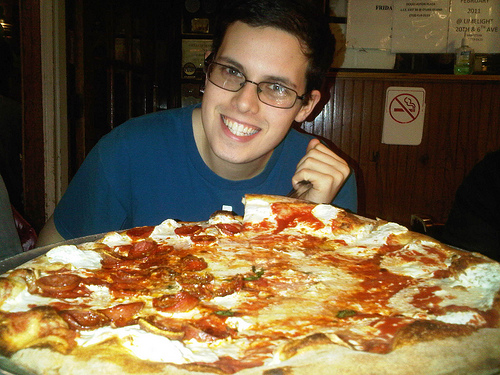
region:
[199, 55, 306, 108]
Pair of glasses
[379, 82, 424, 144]
No smoking sign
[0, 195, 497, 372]
Pizza on a metal pan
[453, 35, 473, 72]
Bottle of hand sanitizer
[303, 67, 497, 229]
Wall with metal panelling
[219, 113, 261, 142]
Young man's mouth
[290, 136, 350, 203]
Hand holding a metal spatula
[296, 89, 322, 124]
Young man's ear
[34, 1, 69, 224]
White wooden panel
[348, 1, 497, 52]
White laminated papers on the back wall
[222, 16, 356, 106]
boy has dark hair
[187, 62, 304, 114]
boy is wearing glasses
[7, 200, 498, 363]
pizza in front of boy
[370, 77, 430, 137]
red and white no smoking sign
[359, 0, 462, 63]
laminated papers in back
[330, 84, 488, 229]
brown wall around no smoking sign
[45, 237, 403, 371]
white cheese on pizza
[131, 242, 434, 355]
red sauce on pizza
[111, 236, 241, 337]
red pepperoni on pizza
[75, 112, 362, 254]
boy has blue shirt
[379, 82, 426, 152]
A no smoking sign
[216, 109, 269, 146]
Wide smile with white teeth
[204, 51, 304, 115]
A man wearing lead frame glasses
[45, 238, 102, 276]
Mozzarella cheese on a pizza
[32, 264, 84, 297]
A pepperoni slice on an pizza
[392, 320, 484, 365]
A pizza crust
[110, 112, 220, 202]
A person wearing a blue shirt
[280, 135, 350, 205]
A hand holding onto a utensil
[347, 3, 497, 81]
Announcements on a poster board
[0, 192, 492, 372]
A pepperoni pizza pie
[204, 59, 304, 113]
person wearing glasses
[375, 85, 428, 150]
no smoking sign on a wall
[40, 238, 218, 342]
pepperoni on a pizza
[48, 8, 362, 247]
person in a blue t-shirt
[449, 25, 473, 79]
hand sanitizer bottle on a shelf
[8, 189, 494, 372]
large pizza on a silver tray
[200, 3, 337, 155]
person with short, brown hair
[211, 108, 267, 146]
person with a big smile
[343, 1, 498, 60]
three sheets of laminated paper on a wall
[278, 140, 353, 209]
person holding a silver utensil in their hand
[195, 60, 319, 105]
glasses on boy's face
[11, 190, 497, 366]
large pizza with mozzarella cheese and tomato sauce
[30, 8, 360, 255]
boy in blue shirt with dark curly hair smiling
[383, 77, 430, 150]
white and red no smoking sign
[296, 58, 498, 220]
brown wooden wall made with planks in background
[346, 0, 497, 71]
notices and announcements in plastic covers on wall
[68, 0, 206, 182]
wooden door opening to kitchen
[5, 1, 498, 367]
indoor restaurant scene in Italian restaurant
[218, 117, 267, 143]
white straight teeth of boy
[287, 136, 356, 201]
hand of boy holding spatula for lifting pizza